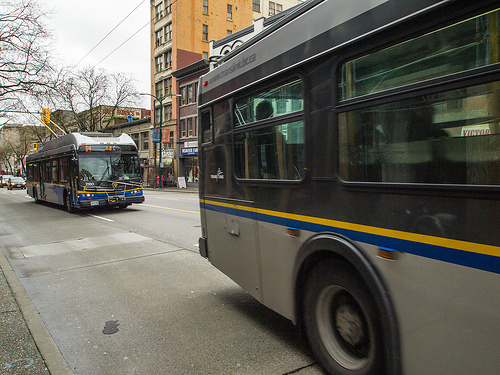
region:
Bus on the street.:
[20, 128, 155, 217]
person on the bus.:
[244, 96, 296, 183]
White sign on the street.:
[175, 173, 188, 190]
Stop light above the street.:
[38, 105, 56, 125]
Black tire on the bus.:
[295, 250, 387, 373]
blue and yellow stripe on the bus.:
[195, 193, 498, 275]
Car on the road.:
[5, 174, 25, 189]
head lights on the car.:
[8, 180, 25, 189]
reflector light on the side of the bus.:
[373, 240, 399, 264]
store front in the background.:
[179, 153, 199, 186]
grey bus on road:
[182, 0, 490, 372]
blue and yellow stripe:
[191, 183, 496, 297]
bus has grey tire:
[291, 271, 449, 361]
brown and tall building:
[134, 3, 222, 120]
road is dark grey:
[15, 228, 192, 372]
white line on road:
[55, 204, 155, 254]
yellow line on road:
[118, 168, 229, 236]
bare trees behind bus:
[4, 9, 135, 136]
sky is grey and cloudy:
[31, 2, 126, 106]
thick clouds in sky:
[21, 3, 145, 87]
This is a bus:
[20, 117, 173, 235]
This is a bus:
[188, 3, 495, 369]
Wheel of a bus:
[287, 220, 389, 372]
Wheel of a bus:
[61, 184, 78, 220]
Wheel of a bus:
[28, 185, 43, 206]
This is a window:
[178, 84, 186, 106]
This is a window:
[186, 83, 195, 104]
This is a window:
[186, 114, 195, 136]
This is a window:
[163, 77, 171, 97]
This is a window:
[162, 104, 172, 122]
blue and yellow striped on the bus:
[406, 228, 496, 273]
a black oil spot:
[94, 305, 131, 340]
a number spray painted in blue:
[1, 353, 37, 372]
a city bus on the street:
[16, 132, 154, 210]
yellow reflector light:
[376, 242, 400, 261]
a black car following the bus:
[6, 176, 28, 195]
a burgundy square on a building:
[173, 41, 203, 68]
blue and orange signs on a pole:
[149, 125, 176, 144]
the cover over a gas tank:
[220, 205, 267, 243]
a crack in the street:
[286, 355, 308, 374]